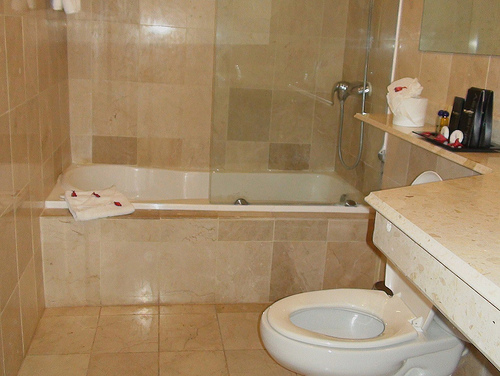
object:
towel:
[64, 189, 137, 222]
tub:
[38, 160, 386, 308]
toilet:
[255, 168, 473, 375]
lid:
[383, 169, 445, 333]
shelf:
[355, 104, 499, 175]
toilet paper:
[386, 77, 429, 128]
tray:
[412, 129, 499, 152]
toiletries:
[449, 95, 465, 142]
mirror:
[418, 1, 499, 57]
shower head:
[330, 80, 355, 105]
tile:
[158, 312, 225, 351]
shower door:
[210, 2, 401, 209]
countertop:
[361, 173, 499, 313]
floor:
[90, 313, 161, 353]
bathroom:
[1, 0, 499, 374]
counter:
[364, 173, 499, 370]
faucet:
[328, 80, 370, 106]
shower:
[40, 1, 401, 307]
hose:
[336, 99, 347, 167]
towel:
[48, 0, 87, 15]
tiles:
[90, 135, 136, 165]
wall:
[64, 1, 367, 177]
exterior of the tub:
[40, 206, 392, 308]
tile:
[270, 241, 328, 305]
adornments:
[72, 190, 79, 196]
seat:
[266, 287, 415, 348]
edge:
[349, 113, 384, 133]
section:
[416, 52, 452, 105]